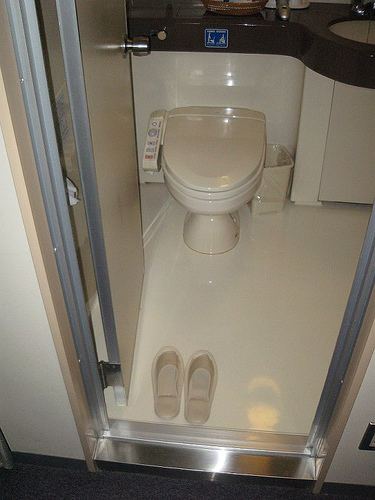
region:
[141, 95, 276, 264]
White toilet in the room.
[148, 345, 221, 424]
Shoes on the floor.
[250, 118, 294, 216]
Trash can beside the toilet.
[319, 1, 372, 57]
Sink in the room.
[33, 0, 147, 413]
Door to the room.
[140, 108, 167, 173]
Buttons on the panel.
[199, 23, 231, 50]
Blue and white sign in the room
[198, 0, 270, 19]
Basket on the counter.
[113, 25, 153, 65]
Silver colored knob on the door.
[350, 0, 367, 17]
Silver colored faucet on the sink.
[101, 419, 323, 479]
Silver threshold of door.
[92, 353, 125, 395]
Silver hinge on door.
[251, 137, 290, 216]
A small beige trash can.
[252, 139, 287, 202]
Clear liner in trash can.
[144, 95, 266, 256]
A beige toilet.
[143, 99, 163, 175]
Controls on toilet.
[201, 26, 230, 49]
A small square sign.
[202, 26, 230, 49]
A blue and white sign.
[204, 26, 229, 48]
Instructions for using toilet.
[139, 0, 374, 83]
A black counter top.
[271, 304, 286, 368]
There is a light, white surface here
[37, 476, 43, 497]
There is some gray flooring here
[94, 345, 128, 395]
There is door hinge right here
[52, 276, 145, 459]
This photo is owned by Zander Zane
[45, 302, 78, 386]
There is some light brown trim here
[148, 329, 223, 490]
cream house shoes near a doorway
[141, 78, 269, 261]
cream toilet with the cover down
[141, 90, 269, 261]
cream toilet with controls next to it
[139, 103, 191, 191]
control buttons on a toilet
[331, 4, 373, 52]
part of a round sink with a black counter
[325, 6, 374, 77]
part of a round sink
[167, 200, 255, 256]
bottom of a cream toilet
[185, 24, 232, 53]
blue and white sign on a black surface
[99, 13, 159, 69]
silver door knob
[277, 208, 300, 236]
Small section of white flooring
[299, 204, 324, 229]
Small section of white flooring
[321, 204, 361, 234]
Small section of white flooring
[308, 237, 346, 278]
Small section of white flooring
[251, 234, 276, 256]
Small section of white flooring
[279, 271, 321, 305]
Small section of white flooring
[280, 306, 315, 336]
Small section of white flooring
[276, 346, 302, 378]
Small section of white flooring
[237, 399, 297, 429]
Small section of white flooring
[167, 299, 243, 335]
Small section of white flooring